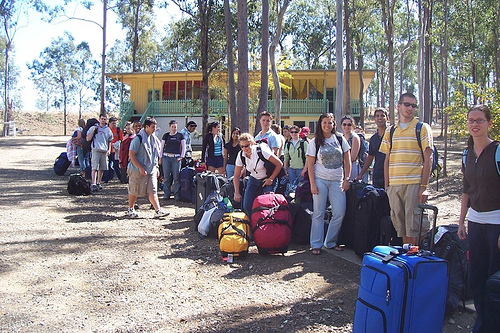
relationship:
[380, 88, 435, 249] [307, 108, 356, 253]
person in line with camper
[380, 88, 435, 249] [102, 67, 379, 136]
person outside cabin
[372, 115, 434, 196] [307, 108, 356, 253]
shirt on camper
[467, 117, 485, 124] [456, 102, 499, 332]
glasses on girl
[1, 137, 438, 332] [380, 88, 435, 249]
road by person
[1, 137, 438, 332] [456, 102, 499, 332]
road by girl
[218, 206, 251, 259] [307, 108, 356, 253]
bag by camper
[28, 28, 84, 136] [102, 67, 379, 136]
tree by cabin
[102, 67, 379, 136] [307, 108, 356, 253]
cabin by camper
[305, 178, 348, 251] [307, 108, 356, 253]
jeans on camper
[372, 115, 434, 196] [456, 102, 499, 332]
shirt by girl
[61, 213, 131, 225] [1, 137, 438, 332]
shadow on road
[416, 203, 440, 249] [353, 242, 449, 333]
handle on luggage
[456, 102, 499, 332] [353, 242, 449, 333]
girl by luggage